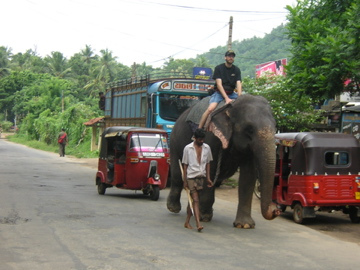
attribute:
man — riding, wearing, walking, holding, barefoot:
[197, 41, 266, 114]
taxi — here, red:
[104, 116, 187, 191]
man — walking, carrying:
[167, 124, 207, 214]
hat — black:
[218, 44, 254, 66]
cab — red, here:
[289, 126, 349, 214]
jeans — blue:
[209, 89, 239, 106]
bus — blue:
[122, 76, 177, 118]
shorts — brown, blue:
[180, 174, 234, 199]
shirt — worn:
[213, 65, 256, 93]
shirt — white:
[180, 142, 224, 174]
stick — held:
[172, 162, 215, 243]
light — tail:
[303, 178, 339, 203]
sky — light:
[68, 6, 174, 45]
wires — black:
[183, 2, 287, 24]